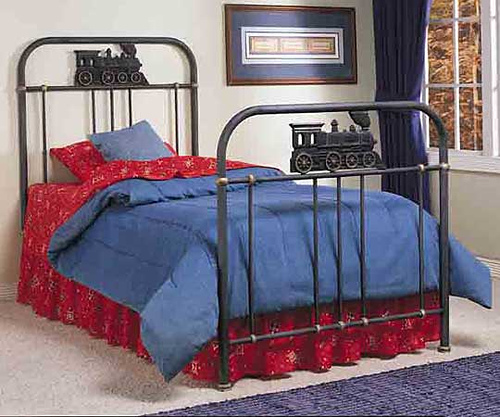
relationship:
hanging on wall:
[225, 7, 365, 91] [214, 5, 391, 127]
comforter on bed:
[92, 165, 211, 299] [19, 35, 449, 365]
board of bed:
[223, 102, 452, 358] [28, 28, 427, 388]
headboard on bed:
[8, 31, 204, 176] [12, 111, 499, 392]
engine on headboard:
[68, 36, 155, 94] [8, 31, 204, 176]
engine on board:
[281, 104, 391, 182] [223, 102, 452, 358]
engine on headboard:
[68, 36, 155, 94] [12, 29, 202, 201]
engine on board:
[285, 104, 387, 178] [223, 102, 452, 358]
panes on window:
[419, 0, 497, 169] [406, 5, 498, 172]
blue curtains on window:
[372, 1, 431, 215] [370, 2, 499, 174]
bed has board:
[12, 27, 461, 397] [223, 102, 452, 358]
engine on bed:
[285, 104, 387, 178] [12, 27, 461, 397]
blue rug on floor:
[157, 359, 482, 414] [1, 273, 495, 414]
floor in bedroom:
[4, 349, 140, 414] [3, 1, 484, 398]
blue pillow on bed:
[86, 119, 174, 163] [12, 27, 461, 397]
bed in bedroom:
[12, 27, 461, 397] [3, 1, 484, 398]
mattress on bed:
[12, 149, 466, 390] [12, 27, 461, 397]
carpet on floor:
[13, 344, 145, 414] [2, 329, 498, 409]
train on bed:
[68, 36, 157, 90] [12, 27, 461, 397]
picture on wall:
[215, 0, 367, 94] [182, 0, 380, 161]